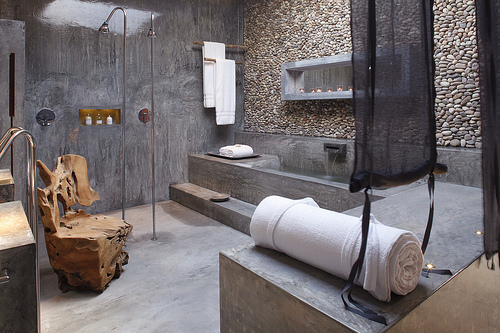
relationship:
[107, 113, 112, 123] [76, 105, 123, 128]
bottle on shelf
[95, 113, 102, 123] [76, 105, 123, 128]
bottle on shelf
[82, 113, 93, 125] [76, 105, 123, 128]
bottle on shelf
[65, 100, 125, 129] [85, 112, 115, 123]
shelf of toiletries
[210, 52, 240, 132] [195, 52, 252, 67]
towel on rack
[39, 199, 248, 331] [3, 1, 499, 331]
gray floor in bathroom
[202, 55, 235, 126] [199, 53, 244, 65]
towel on rack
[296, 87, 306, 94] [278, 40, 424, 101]
candle on shelf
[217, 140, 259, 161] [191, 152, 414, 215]
towel by bath tub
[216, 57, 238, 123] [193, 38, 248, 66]
towel hanging on a rod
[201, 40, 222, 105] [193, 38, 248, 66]
towel hanging on a rod